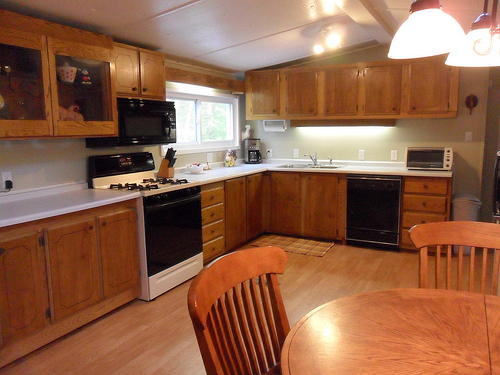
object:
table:
[281, 287, 500, 374]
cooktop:
[89, 169, 201, 197]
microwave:
[86, 97, 177, 146]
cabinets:
[0, 9, 166, 138]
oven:
[406, 146, 453, 170]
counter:
[0, 150, 453, 230]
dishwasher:
[343, 174, 400, 250]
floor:
[0, 231, 500, 374]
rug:
[251, 232, 334, 257]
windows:
[1, 42, 114, 121]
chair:
[187, 244, 291, 373]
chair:
[408, 220, 500, 295]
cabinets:
[245, 58, 459, 121]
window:
[167, 97, 234, 142]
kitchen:
[0, 0, 500, 374]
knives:
[157, 147, 177, 176]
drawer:
[201, 186, 226, 206]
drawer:
[201, 202, 225, 227]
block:
[157, 160, 175, 179]